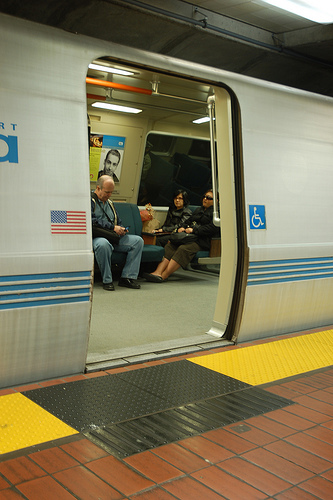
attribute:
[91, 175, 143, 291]
man — here, light-skinned, seated, inside, sitting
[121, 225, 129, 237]
phone — here, black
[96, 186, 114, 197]
spectacle — here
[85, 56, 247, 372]
door — here, open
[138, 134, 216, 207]
window — here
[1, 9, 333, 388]
train — here, white, electric, grey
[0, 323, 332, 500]
ground — here, tiled, orange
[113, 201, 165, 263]
chair — here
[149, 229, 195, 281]
legs — crossed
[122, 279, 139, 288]
shoe — black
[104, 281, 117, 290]
shoe — black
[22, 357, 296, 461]
mat — here, metal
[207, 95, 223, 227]
pole — here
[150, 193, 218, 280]
person — inside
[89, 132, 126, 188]
poster — blue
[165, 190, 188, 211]
hair — black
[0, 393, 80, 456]
line — yellow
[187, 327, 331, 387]
line — yellow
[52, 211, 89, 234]
flag — american, decal, red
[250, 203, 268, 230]
sign — blue, handicapped sign